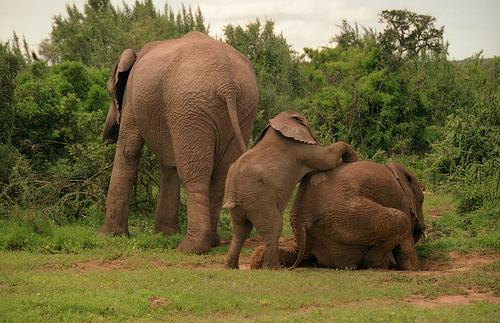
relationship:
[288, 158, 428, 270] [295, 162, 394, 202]
elephant has back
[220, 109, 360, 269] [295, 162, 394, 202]
elephant climbing on back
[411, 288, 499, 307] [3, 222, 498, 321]
patch in grass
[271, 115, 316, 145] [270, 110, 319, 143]
ear on head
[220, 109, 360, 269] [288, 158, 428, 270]
elephant on top of elephant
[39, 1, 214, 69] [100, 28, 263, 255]
tree behind elephant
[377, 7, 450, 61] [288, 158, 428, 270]
tree behind elephant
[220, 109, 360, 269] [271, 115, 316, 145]
elephant has ear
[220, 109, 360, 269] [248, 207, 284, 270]
elephant has leg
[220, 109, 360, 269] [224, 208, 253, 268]
elephant has leg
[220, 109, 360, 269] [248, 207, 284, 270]
elephant standing on leg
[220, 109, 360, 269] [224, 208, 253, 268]
elephant standing on leg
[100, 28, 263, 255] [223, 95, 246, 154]
elephant has tail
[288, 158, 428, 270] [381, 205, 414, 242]
elephant has knee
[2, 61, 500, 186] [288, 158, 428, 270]
brush behind elephant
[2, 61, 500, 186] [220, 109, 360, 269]
brush behind elephant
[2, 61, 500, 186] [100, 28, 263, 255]
brush behind elephant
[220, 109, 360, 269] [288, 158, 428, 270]
elephant on elephant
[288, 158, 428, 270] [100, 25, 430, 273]
elephant in herd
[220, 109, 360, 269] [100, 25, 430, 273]
elephant in herd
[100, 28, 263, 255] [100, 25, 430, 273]
elephant in herd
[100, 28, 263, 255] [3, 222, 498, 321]
elephant on grass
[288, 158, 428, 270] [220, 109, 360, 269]
elephant plays with elephant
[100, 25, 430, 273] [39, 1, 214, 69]
herd in front of tree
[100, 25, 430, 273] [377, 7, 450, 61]
herd in front of tree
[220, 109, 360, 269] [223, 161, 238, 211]
elephant has tail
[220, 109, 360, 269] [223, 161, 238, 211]
elephant wags tail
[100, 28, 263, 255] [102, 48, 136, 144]
elephant has ear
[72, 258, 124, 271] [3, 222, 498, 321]
patch in grass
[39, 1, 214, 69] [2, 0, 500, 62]
tree in front of sky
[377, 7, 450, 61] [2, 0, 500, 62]
tree in front of sky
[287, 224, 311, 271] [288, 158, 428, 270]
tail of elephant